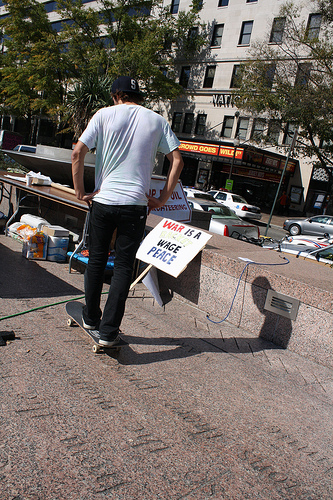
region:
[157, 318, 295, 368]
man's shadow cast on the ground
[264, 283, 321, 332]
small silver grate on side of sidewalk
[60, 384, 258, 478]
prints in the ground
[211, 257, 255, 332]
large shiny blue hose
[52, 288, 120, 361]
large black skate board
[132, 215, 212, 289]
large white square sign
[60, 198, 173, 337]
man wearing blue jeans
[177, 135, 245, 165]
red and orange sign on building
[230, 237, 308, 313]
red edge of wall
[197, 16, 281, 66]
black windows in building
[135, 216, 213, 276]
War is a Wage Peace white sign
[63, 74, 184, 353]
man wearing a blue baseball cap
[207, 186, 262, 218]
police car parked beside the curb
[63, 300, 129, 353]
black skateboard under the man's feet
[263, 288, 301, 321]
aluminum vent on the wall outdoors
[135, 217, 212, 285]
white picket sign against a small retaining wall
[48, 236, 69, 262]
paper towels under a table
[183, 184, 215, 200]
top of a police car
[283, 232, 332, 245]
hood of a police officer's car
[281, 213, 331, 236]
silver car parked behind a police car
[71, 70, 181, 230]
guy with hands on hips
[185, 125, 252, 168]
orange trim with yellow writing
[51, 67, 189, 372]
guy standing on skateboard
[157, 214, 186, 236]
red letters on white background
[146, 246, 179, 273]
blue letters on white background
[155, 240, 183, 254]
black letters on white background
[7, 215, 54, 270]
white, orange, and blue packaging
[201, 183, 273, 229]
police car in roadway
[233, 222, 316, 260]
bicycle is black framed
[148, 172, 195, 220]
red and white sign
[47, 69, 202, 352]
man standing on skateboard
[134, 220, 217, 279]
protest sign on pole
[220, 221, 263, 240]
brake lights on back of car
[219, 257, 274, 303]
blue wire hanging from wall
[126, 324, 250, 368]
shadow of skateboarder on ground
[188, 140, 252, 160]
yellow words on awning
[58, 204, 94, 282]
legs of folding table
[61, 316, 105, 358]
wheels on bottom of skateboard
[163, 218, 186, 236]
red word on sign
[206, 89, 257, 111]
letters on front of building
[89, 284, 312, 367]
Shadow of man on skateboard.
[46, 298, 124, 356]
Black skateboard with grey wheels.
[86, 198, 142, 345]
Black pair of slacks.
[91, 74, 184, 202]
Man wearing white t-shirt.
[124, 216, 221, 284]
Protest sign on stick.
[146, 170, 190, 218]
Sign beside road.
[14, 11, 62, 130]
Lush green trees beside road.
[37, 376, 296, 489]
Cement walk with markings.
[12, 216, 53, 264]
Storage containers.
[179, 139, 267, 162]
Red and yellow sign on building.